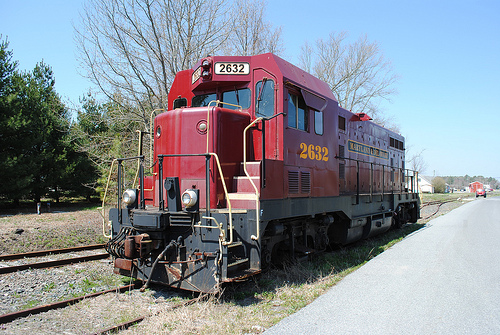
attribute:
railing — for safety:
[157, 151, 214, 230]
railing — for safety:
[116, 153, 146, 218]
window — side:
[286, 85, 306, 132]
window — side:
[314, 109, 327, 136]